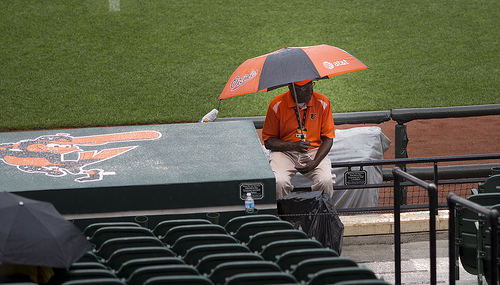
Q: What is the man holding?
A: An umbrella.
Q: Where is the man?
A: A stadium.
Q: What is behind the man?
A: Grass.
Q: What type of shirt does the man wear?
A: A polo.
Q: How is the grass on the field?
A: Manicured.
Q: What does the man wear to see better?
A: Glasses.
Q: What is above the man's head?
A: Umbrella.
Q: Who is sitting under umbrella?
A: Man in orange.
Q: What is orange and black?
A: Umbrella.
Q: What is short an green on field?
A: Grass.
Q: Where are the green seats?
A: In stands.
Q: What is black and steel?
A: Railing.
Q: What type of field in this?
A: Baseball field.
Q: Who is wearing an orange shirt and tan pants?
A: Man under umbrella.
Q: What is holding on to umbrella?
A: Hands of man.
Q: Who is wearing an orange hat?
A: Man with striped umbrella.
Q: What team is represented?
A: Orioles.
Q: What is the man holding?
A: Umbrella.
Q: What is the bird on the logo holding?
A: Baseball bat.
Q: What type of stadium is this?
A: Baseball.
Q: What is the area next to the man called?
A: Dugout.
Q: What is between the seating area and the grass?
A: Dirt.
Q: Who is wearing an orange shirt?
A: Man with the umbrella.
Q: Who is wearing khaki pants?
A: The man.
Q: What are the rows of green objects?
A: Seats.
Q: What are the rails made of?
A: Metal.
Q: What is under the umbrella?
A: Green seats.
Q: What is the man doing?
A: Sitting on a rail.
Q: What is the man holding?
A: A black and orange umbrella.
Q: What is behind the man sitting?
A: A ball field.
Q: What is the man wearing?
A: A orange shirt and tan pants.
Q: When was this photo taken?
A: Daytime.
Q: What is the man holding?
A: An umbrella.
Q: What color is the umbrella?
A: Orange and blue.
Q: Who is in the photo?
A: A man.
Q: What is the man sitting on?
A: A rail.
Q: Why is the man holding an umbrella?
A: It is raining.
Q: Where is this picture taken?
A: A baseball stadium.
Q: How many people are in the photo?
A: One.